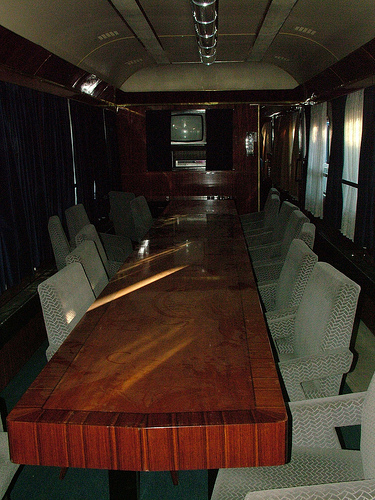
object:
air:
[106, 468, 141, 498]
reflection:
[64, 236, 194, 400]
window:
[337, 88, 369, 242]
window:
[302, 102, 328, 221]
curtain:
[338, 91, 363, 241]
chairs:
[246, 200, 294, 252]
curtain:
[0, 78, 148, 311]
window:
[1, 69, 142, 293]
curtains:
[304, 107, 329, 219]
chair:
[38, 261, 97, 363]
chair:
[65, 240, 109, 299]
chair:
[126, 196, 155, 237]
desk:
[7, 198, 290, 471]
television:
[169, 108, 208, 146]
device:
[172, 157, 208, 167]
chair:
[258, 236, 318, 314]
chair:
[253, 222, 315, 287]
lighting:
[190, 0, 217, 68]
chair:
[263, 261, 360, 401]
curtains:
[263, 100, 306, 207]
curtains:
[146, 110, 171, 170]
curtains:
[203, 107, 234, 170]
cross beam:
[289, 80, 372, 98]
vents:
[294, 26, 317, 36]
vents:
[275, 55, 291, 61]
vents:
[97, 28, 118, 40]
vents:
[125, 58, 143, 65]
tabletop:
[9, 221, 288, 423]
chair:
[209, 368, 375, 498]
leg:
[108, 468, 139, 498]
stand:
[133, 106, 259, 198]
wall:
[131, 92, 233, 171]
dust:
[121, 333, 155, 366]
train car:
[2, 0, 371, 500]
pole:
[254, 98, 261, 214]